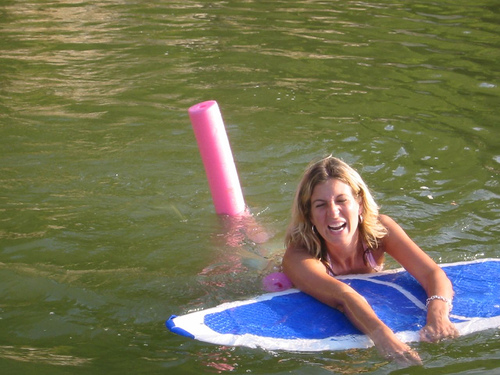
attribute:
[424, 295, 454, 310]
bracelet — metal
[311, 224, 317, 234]
earring — metal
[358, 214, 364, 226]
earring — metal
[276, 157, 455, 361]
blond woman — blonde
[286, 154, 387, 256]
hair — blonde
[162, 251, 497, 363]
surfboard — blue, white trim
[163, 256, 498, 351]
surfboard — blue, white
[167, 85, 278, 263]
foam — pink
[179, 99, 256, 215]
pool noodle — pink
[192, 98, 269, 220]
tube — pink